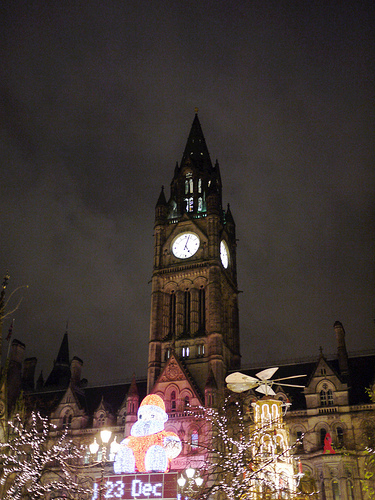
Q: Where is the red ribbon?
A: On the bottom right.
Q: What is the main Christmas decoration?
A: Santa Claus.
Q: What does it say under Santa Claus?
A: 23 Dec.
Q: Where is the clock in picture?
A: In the middle.